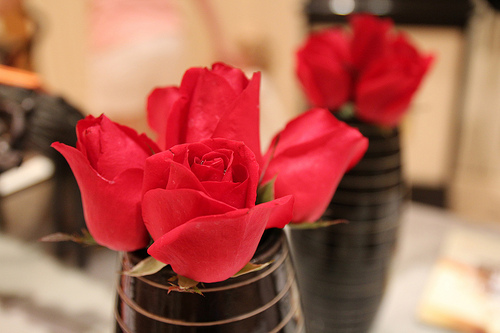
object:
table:
[0, 198, 500, 333]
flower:
[260, 106, 372, 224]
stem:
[256, 177, 279, 206]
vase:
[109, 226, 303, 333]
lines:
[118, 248, 293, 294]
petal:
[313, 134, 359, 183]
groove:
[286, 112, 408, 141]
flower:
[140, 136, 294, 284]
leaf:
[287, 216, 349, 235]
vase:
[288, 111, 410, 331]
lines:
[114, 274, 288, 328]